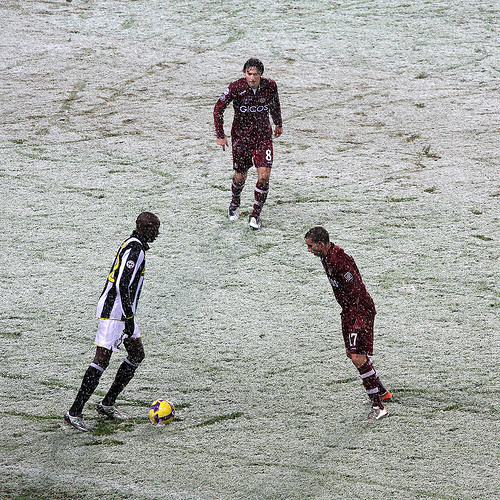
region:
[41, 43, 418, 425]
soccer in the rain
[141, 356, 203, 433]
a yellow and purple soccer ball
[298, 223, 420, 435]
maroon soccer uniform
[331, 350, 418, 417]
maroon socks with white stripes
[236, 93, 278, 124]
white letters across shirt chest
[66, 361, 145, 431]
black knee socks with white edge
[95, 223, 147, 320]
black and white jersey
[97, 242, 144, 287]
yellow print on striped shirt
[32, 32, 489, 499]
flooded soccer field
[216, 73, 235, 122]
team logo on shirt sleeve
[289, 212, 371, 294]
the head of a man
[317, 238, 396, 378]
a man wearing red shorts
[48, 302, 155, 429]
a man wearing white shorts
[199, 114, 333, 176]
a man wearing shorts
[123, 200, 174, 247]
the bald head of a man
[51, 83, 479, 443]
men playing soccer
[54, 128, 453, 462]
men playing soccer in the snow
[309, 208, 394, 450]
a man wearing red uniform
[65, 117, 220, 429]
a man wearing a white and black uniform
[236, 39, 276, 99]
the hair of a man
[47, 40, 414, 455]
three men playing soccer in the snow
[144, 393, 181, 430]
a purple and yellow soccer ball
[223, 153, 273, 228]
the legs of a man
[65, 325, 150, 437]
the legs of a man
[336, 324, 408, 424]
the legs of a man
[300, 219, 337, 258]
the head of a man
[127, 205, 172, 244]
the head of a man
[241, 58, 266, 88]
the head of a man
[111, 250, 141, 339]
the arm of a man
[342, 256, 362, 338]
the arm of a man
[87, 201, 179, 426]
Man playing soccer in the snow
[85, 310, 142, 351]
Man wearing white shorts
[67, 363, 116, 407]
man wearing black socks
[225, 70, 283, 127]
Man wearing a red shirt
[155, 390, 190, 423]
yellow soccer ball on the field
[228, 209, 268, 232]
man wearing white sneakers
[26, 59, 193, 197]
Snow on the field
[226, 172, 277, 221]
Man wearing red socks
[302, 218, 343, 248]
man with brown hair